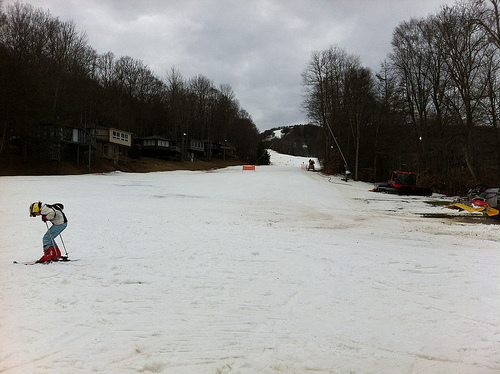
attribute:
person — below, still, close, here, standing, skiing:
[18, 193, 82, 270]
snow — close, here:
[323, 227, 407, 310]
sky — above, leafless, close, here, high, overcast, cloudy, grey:
[177, 5, 304, 75]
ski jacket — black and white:
[37, 200, 70, 230]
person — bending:
[23, 195, 76, 273]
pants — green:
[43, 217, 58, 257]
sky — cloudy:
[11, 2, 483, 153]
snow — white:
[29, 133, 469, 372]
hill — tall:
[264, 147, 323, 182]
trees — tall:
[316, 28, 482, 193]